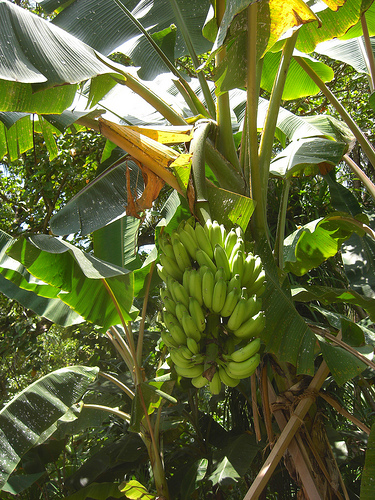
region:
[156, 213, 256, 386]
A bushel of bananas.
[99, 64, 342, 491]
A banana tree in forest.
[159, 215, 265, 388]
A bunch of green bananas.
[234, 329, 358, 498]
A piece of wood on a tree.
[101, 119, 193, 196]
A yellow banana leaf.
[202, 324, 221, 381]
A stem on bunch of bananas.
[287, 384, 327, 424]
A rope around a stick.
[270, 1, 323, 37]
A sunlit banana tree. leaf.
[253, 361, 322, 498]
Two pieces of wood crossed.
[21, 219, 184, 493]
A tree next to a banana tree.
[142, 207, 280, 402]
Handle of bananas in a tree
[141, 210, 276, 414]
bananas are green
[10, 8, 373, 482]
tree of bananas in a field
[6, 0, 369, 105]
big leaves of bananas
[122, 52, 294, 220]
stems of banana tree are green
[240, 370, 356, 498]
dry leaves of banana tree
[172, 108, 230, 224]
stem holding handles of bananas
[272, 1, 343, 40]
a yellow leave of banana tree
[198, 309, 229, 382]
a stem green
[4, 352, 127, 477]
a leave color dark green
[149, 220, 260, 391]
Bunch of banana fruit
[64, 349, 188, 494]
Green banana tree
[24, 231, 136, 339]
Large leaf of banana tree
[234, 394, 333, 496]
Planks of wood holding up a banana trunk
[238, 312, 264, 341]
One banana fruit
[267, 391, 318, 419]
Pieces of rope tied to wooden planks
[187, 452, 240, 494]
Rays of light on banana leaves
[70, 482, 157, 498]
Browning banana leaves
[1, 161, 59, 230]
Twigs in the background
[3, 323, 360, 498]
Banana farm with ripening bananas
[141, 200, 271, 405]
bananas growing from a tree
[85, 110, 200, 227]
dead leaf on a banana tree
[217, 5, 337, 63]
yellow banana leaves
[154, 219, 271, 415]
bunches of unripe bananas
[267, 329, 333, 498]
wooden post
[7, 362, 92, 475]
water spots on a banana leaf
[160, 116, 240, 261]
tree branch being pulled down by the weight of the bananas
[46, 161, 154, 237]
spotty leaves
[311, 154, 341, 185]
brown spots on a leaf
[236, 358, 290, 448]
dead wood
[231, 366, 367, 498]
light brown plant stalk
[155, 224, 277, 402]
large bunch of bananas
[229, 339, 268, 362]
small green bananna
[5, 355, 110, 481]
large tropical plant leaf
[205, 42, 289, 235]
large green plant stalks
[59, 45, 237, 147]
large leaf reflecting bright sunlight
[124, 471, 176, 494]
small yellow leaf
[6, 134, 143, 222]
green tree leaves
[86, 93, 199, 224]
light brown dry tropical leaf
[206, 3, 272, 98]
medium tropical leaf with white spots